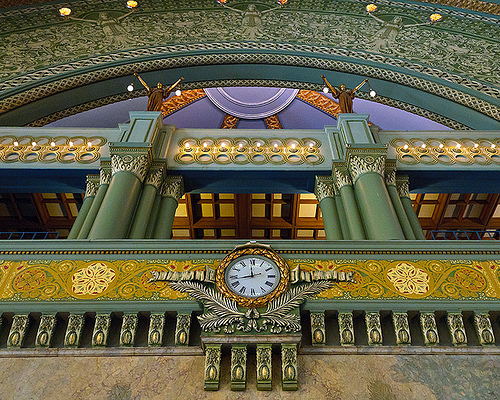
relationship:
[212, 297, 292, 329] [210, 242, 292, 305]
leaves under clock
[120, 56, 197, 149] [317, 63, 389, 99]
brass statue holding lights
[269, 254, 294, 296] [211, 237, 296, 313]
gold trim around clock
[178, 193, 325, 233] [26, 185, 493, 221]
panels in ceiling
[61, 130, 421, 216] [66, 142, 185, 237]
trim on columns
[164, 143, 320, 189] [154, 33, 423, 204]
figures under arch